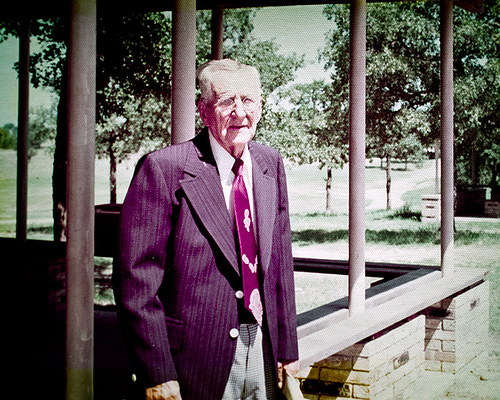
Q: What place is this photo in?
A: It is at the park.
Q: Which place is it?
A: It is a park.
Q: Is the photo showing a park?
A: Yes, it is showing a park.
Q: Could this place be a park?
A: Yes, it is a park.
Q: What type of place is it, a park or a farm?
A: It is a park.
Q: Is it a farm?
A: No, it is a park.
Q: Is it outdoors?
A: Yes, it is outdoors.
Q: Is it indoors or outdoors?
A: It is outdoors.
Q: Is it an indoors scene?
A: No, it is outdoors.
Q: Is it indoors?
A: No, it is outdoors.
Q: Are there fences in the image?
A: No, there are no fences.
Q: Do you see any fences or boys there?
A: No, there are no fences or boys.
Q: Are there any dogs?
A: No, there are no dogs.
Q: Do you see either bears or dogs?
A: No, there are no dogs or bears.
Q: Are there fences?
A: No, there are no fences.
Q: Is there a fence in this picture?
A: No, there are no fences.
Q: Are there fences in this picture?
A: No, there are no fences.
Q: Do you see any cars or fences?
A: No, there are no fences or cars.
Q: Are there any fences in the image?
A: No, there are no fences.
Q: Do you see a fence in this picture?
A: No, there are no fences.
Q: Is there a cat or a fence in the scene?
A: No, there are no fences or cats.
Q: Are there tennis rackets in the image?
A: No, there are no tennis rackets.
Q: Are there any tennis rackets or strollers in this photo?
A: No, there are no tennis rackets or strollers.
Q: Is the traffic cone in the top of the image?
A: No, the traffic cone is in the bottom of the image.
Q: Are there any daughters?
A: No, there are no daughters.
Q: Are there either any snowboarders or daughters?
A: No, there are no daughters or snowboarders.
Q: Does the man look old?
A: Yes, the man is old.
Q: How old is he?
A: The man is old.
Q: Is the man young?
A: No, the man is old.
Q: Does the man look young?
A: No, the man is old.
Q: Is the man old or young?
A: The man is old.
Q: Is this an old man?
A: Yes, this is an old man.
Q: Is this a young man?
A: No, this is an old man.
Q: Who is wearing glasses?
A: The man is wearing glasses.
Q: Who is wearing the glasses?
A: The man is wearing glasses.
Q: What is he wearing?
A: The man is wearing glasses.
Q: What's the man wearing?
A: The man is wearing glasses.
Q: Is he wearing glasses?
A: Yes, the man is wearing glasses.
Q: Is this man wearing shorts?
A: No, the man is wearing glasses.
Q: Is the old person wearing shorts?
A: No, the man is wearing glasses.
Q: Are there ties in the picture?
A: Yes, there is a tie.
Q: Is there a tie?
A: Yes, there is a tie.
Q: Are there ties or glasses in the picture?
A: Yes, there is a tie.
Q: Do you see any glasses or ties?
A: Yes, there is a tie.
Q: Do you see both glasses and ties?
A: Yes, there are both a tie and glasses.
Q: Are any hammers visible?
A: No, there are no hammers.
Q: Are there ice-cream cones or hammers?
A: No, there are no hammers or ice-cream cones.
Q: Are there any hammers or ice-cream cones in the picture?
A: No, there are no hammers or ice-cream cones.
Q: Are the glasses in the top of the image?
A: Yes, the glasses are in the top of the image.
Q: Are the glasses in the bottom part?
A: No, the glasses are in the top of the image.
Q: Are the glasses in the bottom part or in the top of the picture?
A: The glasses are in the top of the image.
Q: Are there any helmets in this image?
A: No, there are no helmets.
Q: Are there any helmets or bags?
A: No, there are no helmets or bags.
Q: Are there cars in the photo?
A: No, there are no cars.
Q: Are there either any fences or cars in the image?
A: No, there are no cars or fences.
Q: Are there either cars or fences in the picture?
A: No, there are no cars or fences.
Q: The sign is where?
A: The sign is in the park.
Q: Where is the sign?
A: The sign is in the park.